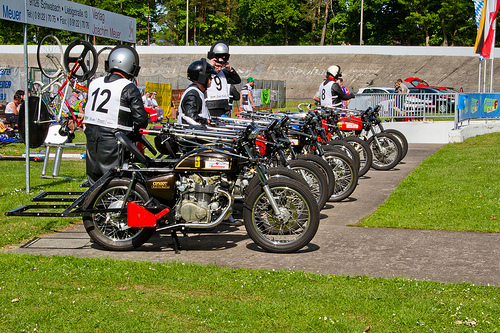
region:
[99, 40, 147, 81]
a gray helmet on the man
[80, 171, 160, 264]
a black motorcycle tire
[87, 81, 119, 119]
a black number on the shirt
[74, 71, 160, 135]
a black and white coat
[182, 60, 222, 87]
a black helmet on the man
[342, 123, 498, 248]
a patch of green grass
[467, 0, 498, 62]
flags behind the grass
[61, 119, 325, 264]
a black motorcycle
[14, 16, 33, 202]
a gray metal pole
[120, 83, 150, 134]
the arm of the man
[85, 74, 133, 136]
White vest with 12 on it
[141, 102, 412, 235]
Row of ten motorcyles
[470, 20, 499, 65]
Red, white, back and yellow flags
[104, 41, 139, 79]
Silver motorcycle helmet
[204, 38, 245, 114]
Rider taking off a motorcycle helmet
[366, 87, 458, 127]
Silver fence in background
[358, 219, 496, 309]
Cement path in the grass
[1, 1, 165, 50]
Sign held up by poles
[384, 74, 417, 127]
People behind a fence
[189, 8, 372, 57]
Trees behind a wall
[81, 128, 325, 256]
A BLACK MOTORCYCLE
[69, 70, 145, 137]
A VEST WITH A 12 ON IT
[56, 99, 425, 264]
A ROW OF MOTORCYCLES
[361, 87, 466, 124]
A METAL FENCE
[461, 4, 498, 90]
TO FLAGS ON THE FAR LEFT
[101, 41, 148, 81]
A GRAY MOTORCYCLE HELMET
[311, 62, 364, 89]
A WHITE MOTORCYCLE HELMET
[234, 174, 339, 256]
A FRONT MOTORCYCLE TIRE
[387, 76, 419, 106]
PEOPLE BEHIND THE FENCE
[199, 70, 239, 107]
WHITE VEST WITH A 9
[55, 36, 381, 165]
men wearing helmets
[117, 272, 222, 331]
green grass next to motorcycles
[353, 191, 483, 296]
gray sidewalk in front of bikes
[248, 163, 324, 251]
black wheels on bikes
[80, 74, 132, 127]
number 12 on person's back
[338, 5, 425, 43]
green trees in background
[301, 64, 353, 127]
number 8 on guys back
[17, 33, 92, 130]
upside down bikes hanging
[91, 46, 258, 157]
three people standing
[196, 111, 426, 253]
row of bikes on the ground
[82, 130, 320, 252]
first bike in the line up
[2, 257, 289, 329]
small grassy area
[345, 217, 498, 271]
part of the sidewalk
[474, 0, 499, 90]
three different flags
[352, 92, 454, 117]
a metal gate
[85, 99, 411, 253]
bikes all lined up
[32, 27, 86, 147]
a couple of hanging bikes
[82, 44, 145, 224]
number 12 bike rider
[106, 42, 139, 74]
black and grey silver helmet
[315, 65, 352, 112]
number eight bike rider